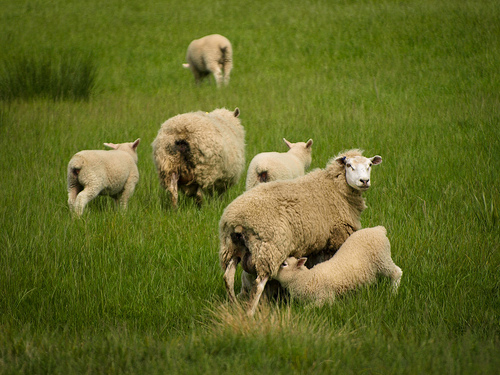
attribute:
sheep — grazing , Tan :
[178, 30, 237, 87]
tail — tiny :
[215, 39, 229, 57]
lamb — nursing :
[272, 221, 402, 310]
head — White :
[335, 150, 387, 185]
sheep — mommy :
[207, 136, 382, 302]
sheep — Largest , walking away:
[148, 104, 250, 199]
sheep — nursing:
[192, 148, 393, 289]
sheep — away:
[178, 20, 285, 104]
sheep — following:
[51, 136, 202, 254]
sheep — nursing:
[284, 196, 413, 324]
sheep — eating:
[149, 27, 274, 123]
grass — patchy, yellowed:
[213, 281, 294, 323]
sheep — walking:
[60, 32, 390, 372]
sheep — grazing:
[154, 30, 237, 98]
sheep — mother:
[98, 90, 265, 198]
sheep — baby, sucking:
[263, 224, 472, 338]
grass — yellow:
[211, 279, 341, 355]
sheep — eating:
[170, 11, 257, 86]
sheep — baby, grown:
[219, 148, 424, 336]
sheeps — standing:
[48, 32, 456, 372]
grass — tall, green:
[5, 39, 115, 109]